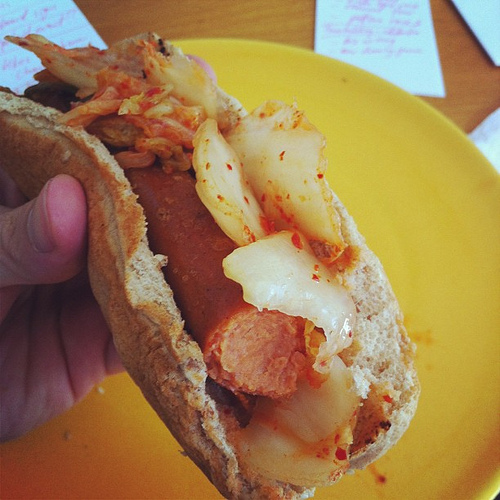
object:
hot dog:
[1, 42, 409, 473]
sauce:
[74, 73, 322, 310]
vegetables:
[206, 112, 338, 306]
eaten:
[203, 335, 375, 460]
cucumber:
[198, 110, 257, 241]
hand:
[1, 182, 124, 442]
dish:
[222, 38, 498, 344]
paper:
[337, 0, 444, 89]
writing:
[342, 8, 425, 57]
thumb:
[5, 175, 86, 299]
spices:
[61, 47, 189, 146]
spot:
[363, 467, 394, 489]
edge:
[249, 62, 445, 89]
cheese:
[30, 23, 163, 108]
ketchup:
[39, 28, 174, 135]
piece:
[152, 380, 213, 450]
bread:
[94, 210, 192, 406]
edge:
[128, 288, 189, 362]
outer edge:
[181, 260, 254, 389]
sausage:
[211, 302, 301, 388]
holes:
[371, 311, 396, 355]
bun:
[154, 313, 388, 471]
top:
[94, 71, 307, 319]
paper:
[26, 0, 88, 34]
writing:
[1, 8, 35, 24]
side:
[5, 188, 19, 400]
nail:
[27, 187, 52, 249]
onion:
[169, 77, 312, 297]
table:
[3, 0, 498, 131]